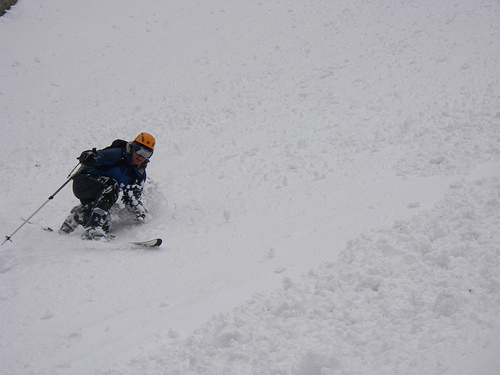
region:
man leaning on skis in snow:
[1, 126, 163, 271]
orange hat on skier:
[116, 126, 161, 149]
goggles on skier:
[133, 143, 154, 161]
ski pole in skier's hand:
[0, 141, 103, 249]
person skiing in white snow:
[13, 133, 168, 268]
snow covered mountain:
[3, 8, 497, 373]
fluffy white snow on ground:
[4, 3, 498, 373]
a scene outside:
[5, 17, 490, 372]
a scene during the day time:
[4, 21, 496, 373]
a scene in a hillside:
[6, 19, 497, 374]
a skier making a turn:
[0, 86, 202, 295]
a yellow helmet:
[124, 120, 166, 162]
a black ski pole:
[0, 143, 104, 257]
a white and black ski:
[16, 211, 175, 259]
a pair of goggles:
[129, 139, 156, 166]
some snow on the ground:
[9, 18, 486, 373]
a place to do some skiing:
[10, 18, 497, 373]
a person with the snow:
[17, 105, 236, 295]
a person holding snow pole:
[7, 138, 97, 244]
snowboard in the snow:
[16, 204, 166, 261]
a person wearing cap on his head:
[128, 128, 163, 159]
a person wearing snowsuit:
[78, 131, 165, 243]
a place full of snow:
[198, 20, 441, 269]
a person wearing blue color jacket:
[91, 141, 151, 206]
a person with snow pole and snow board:
[51, 119, 193, 257]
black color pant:
[73, 171, 117, 231]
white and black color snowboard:
[131, 235, 183, 261]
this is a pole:
[15, 183, 95, 249]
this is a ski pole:
[35, 207, 49, 217]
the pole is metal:
[27, 187, 114, 268]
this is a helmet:
[136, 147, 177, 157]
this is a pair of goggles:
[123, 146, 214, 178]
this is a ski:
[116, 217, 237, 284]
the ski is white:
[109, 228, 334, 299]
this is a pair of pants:
[77, 173, 133, 243]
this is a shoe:
[77, 218, 114, 256]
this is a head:
[112, 142, 234, 171]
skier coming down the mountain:
[6, 119, 175, 264]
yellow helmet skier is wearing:
[134, 132, 161, 149]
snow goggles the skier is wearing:
[130, 144, 157, 161]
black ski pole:
[7, 170, 85, 238]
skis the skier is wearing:
[40, 227, 161, 258]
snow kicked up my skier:
[89, 167, 167, 227]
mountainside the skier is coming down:
[5, 4, 482, 374]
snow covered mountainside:
[5, 4, 495, 374]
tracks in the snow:
[7, 77, 475, 346]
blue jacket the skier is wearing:
[92, 147, 143, 195]